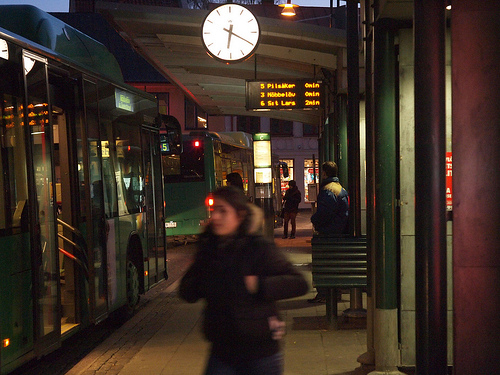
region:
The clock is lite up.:
[179, 1, 280, 78]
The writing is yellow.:
[247, 72, 351, 119]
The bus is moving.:
[6, 51, 184, 316]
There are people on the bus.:
[6, 43, 174, 345]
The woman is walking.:
[180, 183, 307, 371]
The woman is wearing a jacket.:
[176, 172, 313, 372]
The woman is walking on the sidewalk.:
[162, 188, 300, 366]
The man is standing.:
[312, 165, 359, 245]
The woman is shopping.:
[269, 169, 316, 231]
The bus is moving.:
[173, 125, 291, 223]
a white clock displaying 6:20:
[202, 3, 259, 65]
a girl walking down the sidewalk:
[177, 186, 307, 374]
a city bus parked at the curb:
[1, 1, 168, 373]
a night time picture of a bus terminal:
[1, 0, 499, 373]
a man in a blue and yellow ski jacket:
[310, 161, 351, 238]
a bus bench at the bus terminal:
[311, 235, 369, 329]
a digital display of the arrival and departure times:
[243, 77, 336, 115]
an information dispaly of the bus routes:
[253, 133, 273, 206]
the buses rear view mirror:
[160, 113, 185, 155]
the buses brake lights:
[205, 194, 212, 208]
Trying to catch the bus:
[117, 81, 320, 370]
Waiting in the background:
[289, 143, 379, 315]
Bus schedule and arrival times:
[233, 73, 338, 130]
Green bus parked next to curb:
[58, 58, 188, 338]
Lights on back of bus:
[161, 112, 221, 217]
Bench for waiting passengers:
[291, 224, 377, 342]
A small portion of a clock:
[201, 56, 264, 67]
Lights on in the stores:
[246, 140, 326, 233]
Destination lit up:
[107, 81, 156, 127]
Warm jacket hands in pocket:
[171, 190, 313, 360]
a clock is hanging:
[164, 5, 322, 141]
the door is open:
[17, 106, 164, 322]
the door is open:
[9, 118, 93, 298]